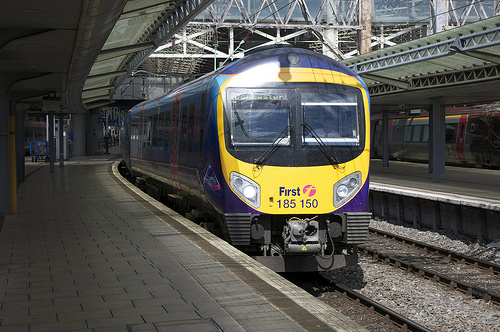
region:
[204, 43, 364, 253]
YELLOW AND BLUE TRAIN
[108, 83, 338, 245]
PART OF A TRAIN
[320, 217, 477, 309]
PART OF TRAIN TRACKS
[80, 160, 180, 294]
PART OF A PLATFORM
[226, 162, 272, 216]
HEADLIGHT ON A TRAIN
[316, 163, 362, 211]
HEADLIGHT ON A TRAIN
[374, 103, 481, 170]
PART OF A TRAIN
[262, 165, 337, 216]
YELLOW BACKGROUND WITH BLUE WRITING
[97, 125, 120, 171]
PERSON ON TRAIN PLATFORM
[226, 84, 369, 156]
WINDOWS ON A TRAIN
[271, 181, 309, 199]
First on the train.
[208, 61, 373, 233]
The front is yellow.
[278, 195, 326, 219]
Numbers on the train.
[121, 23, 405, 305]
The train is on tracks.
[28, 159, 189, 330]
The platform is grey.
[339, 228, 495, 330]
Gravel around the tracks.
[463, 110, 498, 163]
Graffiti on the train.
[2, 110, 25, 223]
A yellow pole on the platform.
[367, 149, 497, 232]
The meridian is made of cement.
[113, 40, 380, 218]
The body of the train is blue.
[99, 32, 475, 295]
a train in a train station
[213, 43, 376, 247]
front a train is yellow and blue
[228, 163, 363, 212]
headlights of train are white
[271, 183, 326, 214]
a number on train 185 150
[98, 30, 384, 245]
car of train is blue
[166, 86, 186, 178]
door of train is red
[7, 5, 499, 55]
ceiling of train station is metal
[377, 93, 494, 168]
a train on right side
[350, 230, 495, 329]
railroad is cover with gravel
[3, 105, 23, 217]
a yellow pole on a platform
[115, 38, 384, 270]
A train in a subway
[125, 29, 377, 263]
The train is purple and yellow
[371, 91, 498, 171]
Grey and red train on another track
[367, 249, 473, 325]
Stones and gravel under railroad track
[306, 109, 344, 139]
Train conductor inside train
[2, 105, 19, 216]
Yellow pole on sidewalk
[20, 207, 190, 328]
Concrete bricks on ground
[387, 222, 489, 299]
Steel railroad tracks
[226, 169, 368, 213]
Front lights of train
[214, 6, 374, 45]
Metal beams on the ceiling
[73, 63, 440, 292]
a train on a subway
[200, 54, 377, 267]
the front part of the train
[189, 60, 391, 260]
the train is blue and yellow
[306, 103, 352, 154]
the motor man is in the window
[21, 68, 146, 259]
a platform next to the train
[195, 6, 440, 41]
infrasturcture above the train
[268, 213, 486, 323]
tracks on teh ground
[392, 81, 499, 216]
another platform besides the train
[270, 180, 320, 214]
the train's ID number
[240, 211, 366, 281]
the motor on the train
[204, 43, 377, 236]
yellow and blue front of train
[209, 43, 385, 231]
yellow and blue front of train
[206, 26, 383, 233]
yellow and blue front of train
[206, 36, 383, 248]
yellow and blue front of train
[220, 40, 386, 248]
yellow and blue front of train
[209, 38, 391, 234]
yellow and blue front of train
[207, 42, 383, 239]
yellow and blue front of train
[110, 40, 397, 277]
train on the tracks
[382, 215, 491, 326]
a set of tracks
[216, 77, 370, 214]
yellow front of train